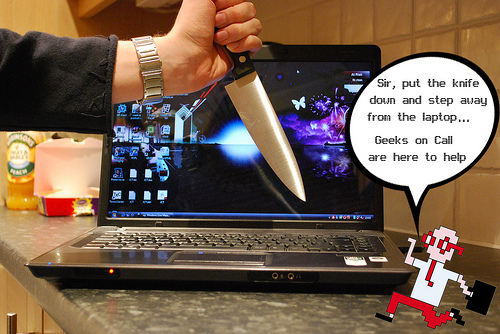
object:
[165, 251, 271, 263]
touch-pad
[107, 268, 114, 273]
power light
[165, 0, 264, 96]
hand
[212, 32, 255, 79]
handle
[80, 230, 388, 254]
keyboard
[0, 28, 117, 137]
sleeve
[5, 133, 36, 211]
peach juice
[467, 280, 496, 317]
suit case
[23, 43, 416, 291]
computer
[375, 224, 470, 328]
man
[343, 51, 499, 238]
quote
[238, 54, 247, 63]
bolt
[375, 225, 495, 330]
character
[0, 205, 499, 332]
counter top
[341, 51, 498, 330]
cartoon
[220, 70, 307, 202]
blade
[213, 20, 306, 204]
knife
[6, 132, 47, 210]
bottle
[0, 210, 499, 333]
counter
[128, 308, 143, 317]
gray stone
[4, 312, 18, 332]
handle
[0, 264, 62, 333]
cabinet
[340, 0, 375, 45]
tile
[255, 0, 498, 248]
wall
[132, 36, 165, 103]
watch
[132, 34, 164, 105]
band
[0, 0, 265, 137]
person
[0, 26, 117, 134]
jacket